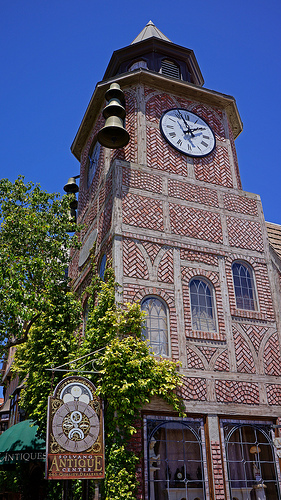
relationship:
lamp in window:
[250, 446, 262, 466] [222, 423, 280, 498]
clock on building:
[158, 107, 214, 158] [0, 19, 280, 494]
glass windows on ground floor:
[143, 416, 207, 497] [105, 401, 278, 498]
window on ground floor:
[222, 423, 280, 498] [105, 401, 278, 498]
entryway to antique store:
[2, 419, 49, 498] [4, 382, 58, 498]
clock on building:
[159, 107, 214, 158] [64, 19, 261, 240]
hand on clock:
[174, 125, 203, 132] [153, 100, 224, 158]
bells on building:
[94, 79, 138, 152] [24, 16, 279, 498]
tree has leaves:
[22, 273, 184, 498] [37, 283, 169, 391]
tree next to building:
[22, 273, 184, 498] [24, 16, 279, 498]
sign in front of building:
[43, 372, 108, 483] [24, 16, 279, 498]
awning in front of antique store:
[1, 418, 48, 467] [0, 327, 106, 498]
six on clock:
[187, 144, 191, 150] [158, 107, 214, 158]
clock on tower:
[159, 107, 214, 158] [70, 13, 245, 186]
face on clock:
[170, 111, 212, 147] [158, 101, 226, 162]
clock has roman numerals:
[159, 107, 214, 158] [170, 114, 211, 149]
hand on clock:
[177, 109, 194, 138] [158, 107, 214, 158]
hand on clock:
[184, 127, 206, 134] [158, 107, 214, 158]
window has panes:
[222, 423, 280, 498] [230, 440, 260, 480]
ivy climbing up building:
[52, 255, 187, 495] [24, 16, 279, 498]